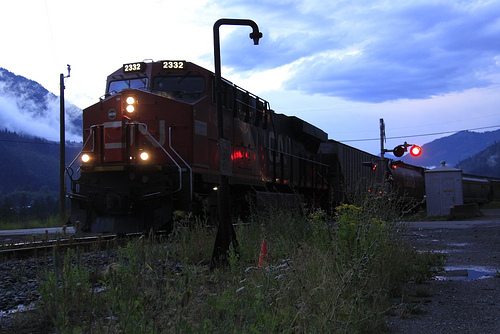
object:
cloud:
[203, 0, 500, 104]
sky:
[0, 0, 499, 158]